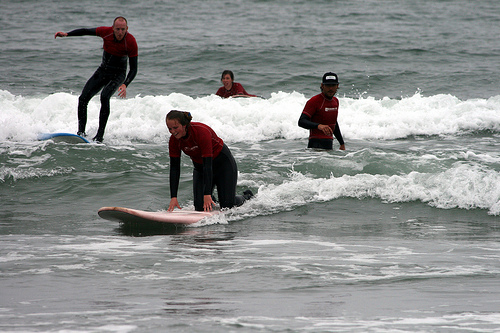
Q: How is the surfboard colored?
A: Blue.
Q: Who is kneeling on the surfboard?
A: A woman.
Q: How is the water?
A: Calm.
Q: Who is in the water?
A: Group of men.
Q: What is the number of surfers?
A: 4.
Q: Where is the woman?
A: Front.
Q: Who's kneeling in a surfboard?
A: A woman.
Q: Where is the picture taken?
A: In the ocean.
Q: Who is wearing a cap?
A: A male surfer.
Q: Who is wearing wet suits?
A: All of the surfers.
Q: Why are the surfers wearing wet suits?
A: The water is cold.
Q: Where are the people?
A: Surfing in the ocean.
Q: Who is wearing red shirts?
A: All of the surfers.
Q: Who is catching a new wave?
A: The surfer directly behind the woman.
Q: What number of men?
A: Two.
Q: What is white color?
A: Wave.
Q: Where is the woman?
A: Surfboard.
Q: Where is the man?
A: Surfboard.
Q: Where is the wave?
A: In ocean.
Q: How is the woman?
A: On knees.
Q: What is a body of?
A: Water.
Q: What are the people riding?
A: Surfboards.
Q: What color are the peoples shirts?
A: Burgundy/dark red.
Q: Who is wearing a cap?
A: Man standing in water.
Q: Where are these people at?
A: Ocean.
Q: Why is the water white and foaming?
A: Breaking waves.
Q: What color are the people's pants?
A: Black.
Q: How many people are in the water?
A: Four.